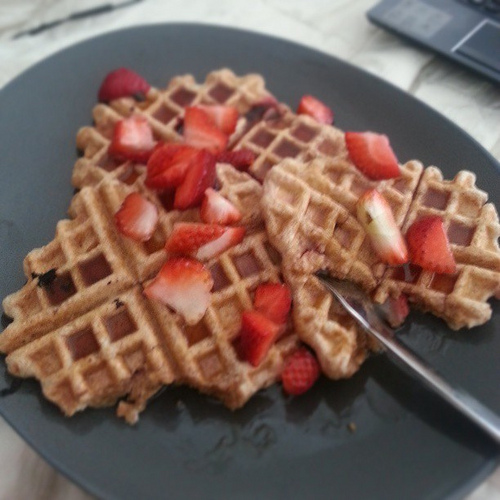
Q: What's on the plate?
A: Waffles and strawberries.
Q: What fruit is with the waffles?
A: Strawberries.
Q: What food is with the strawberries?
A: Waffles.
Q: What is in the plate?
A: Waffles.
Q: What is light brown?
A: Waffles.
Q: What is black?
A: Plate.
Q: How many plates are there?
A: One.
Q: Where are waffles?
A: On a plate.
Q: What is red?
A: Strawberries.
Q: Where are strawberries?
A: On waffles.